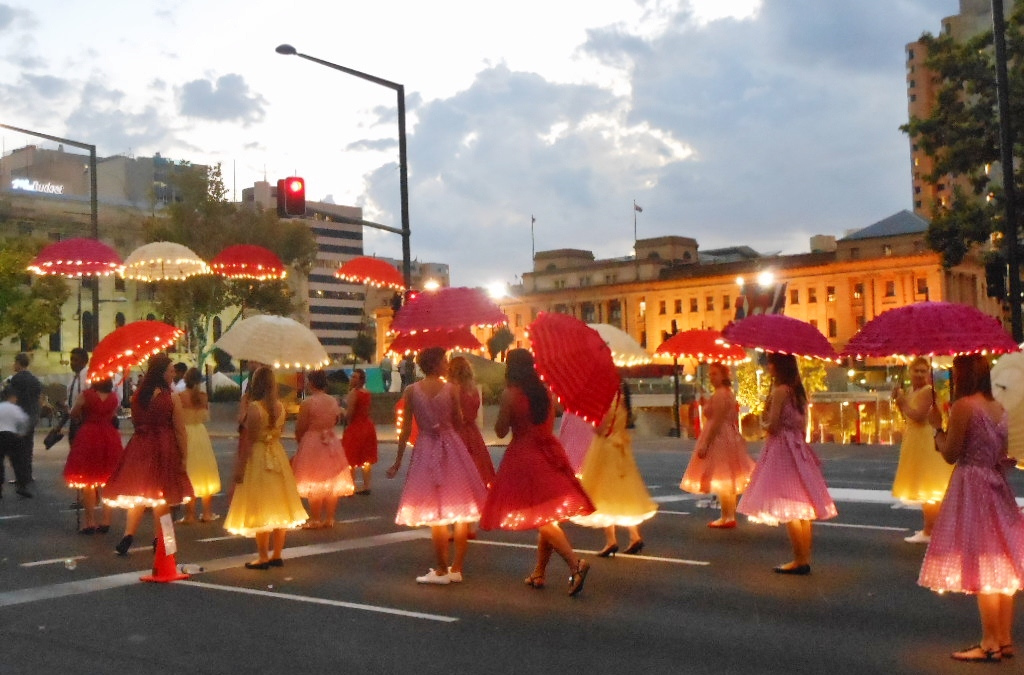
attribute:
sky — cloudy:
[456, 3, 630, 139]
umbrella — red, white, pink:
[535, 316, 621, 427]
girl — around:
[232, 366, 291, 555]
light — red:
[280, 177, 308, 219]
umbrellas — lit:
[28, 231, 286, 279]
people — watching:
[146, 325, 644, 549]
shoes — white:
[420, 564, 464, 585]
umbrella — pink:
[841, 306, 1020, 363]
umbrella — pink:
[28, 236, 120, 280]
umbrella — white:
[122, 244, 208, 279]